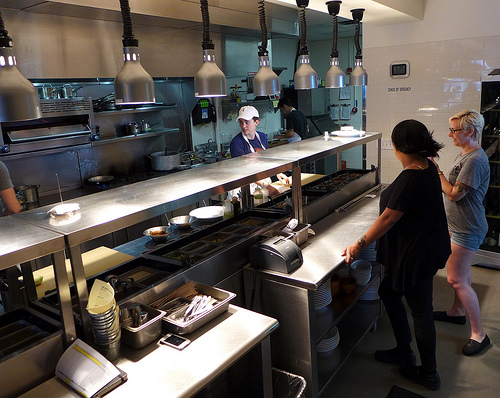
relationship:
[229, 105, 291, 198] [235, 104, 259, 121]
woman has cap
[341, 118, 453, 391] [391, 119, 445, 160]
woman has hair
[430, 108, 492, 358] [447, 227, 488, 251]
woman wearing shorts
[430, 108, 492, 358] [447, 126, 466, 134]
woman wearing glasses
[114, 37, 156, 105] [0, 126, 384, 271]
light over shelf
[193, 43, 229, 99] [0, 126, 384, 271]
light over shelf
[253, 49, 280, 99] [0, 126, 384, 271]
light over shelf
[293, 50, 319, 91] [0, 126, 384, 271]
light over shelf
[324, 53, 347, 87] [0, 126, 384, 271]
light over shelf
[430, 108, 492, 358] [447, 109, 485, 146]
woman has hair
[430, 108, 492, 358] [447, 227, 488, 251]
woman has shorts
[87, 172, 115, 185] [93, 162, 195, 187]
pan on stove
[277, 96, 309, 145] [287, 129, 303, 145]
cook wearing apron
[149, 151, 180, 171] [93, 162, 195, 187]
pot on stove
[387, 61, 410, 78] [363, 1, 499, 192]
clock on wall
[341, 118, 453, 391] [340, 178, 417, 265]
woman has arm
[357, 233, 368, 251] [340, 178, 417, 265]
tattoo on arm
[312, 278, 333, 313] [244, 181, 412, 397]
plates on shelf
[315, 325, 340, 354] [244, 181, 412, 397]
plates on shelf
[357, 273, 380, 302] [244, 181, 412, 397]
plates on shelf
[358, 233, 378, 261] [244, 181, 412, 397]
plates on shelf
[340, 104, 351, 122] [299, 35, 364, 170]
clipboard on wall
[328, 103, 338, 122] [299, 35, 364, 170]
clipboard on wall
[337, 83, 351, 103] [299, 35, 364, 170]
clipboard on wall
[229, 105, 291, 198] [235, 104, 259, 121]
woman wearing cap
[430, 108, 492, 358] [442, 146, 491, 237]
woman wearing shirt